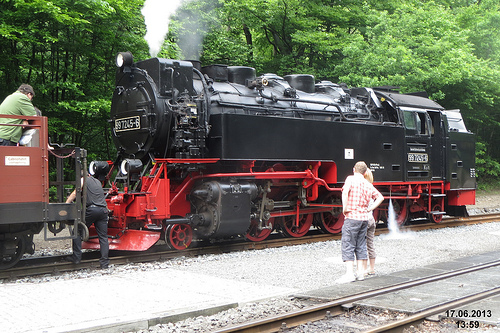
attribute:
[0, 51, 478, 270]
train — stopped, red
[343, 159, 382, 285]
couple — together, talking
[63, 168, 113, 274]
man — sitting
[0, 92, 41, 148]
shirt — light green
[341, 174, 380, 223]
shirt — checkered, plaid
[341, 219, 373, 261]
pants — short, gray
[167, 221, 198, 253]
wheel — red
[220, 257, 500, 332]
tracks — empty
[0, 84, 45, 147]
man — leaning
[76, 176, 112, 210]
shirt — black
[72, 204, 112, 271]
pants — black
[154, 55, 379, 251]
engine — black, red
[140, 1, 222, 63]
steam — being released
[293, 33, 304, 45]
leaf — green